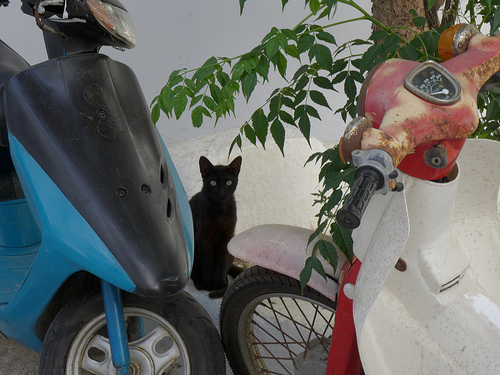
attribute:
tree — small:
[130, 0, 499, 317]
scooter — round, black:
[4, 1, 204, 340]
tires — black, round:
[38, 265, 355, 373]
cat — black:
[177, 157, 261, 271]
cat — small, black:
[186, 153, 249, 286]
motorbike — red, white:
[18, 19, 315, 372]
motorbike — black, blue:
[34, 141, 249, 365]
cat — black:
[181, 155, 265, 289]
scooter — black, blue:
[2, 61, 186, 359]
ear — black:
[195, 150, 212, 172]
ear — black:
[225, 150, 244, 167]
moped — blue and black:
[11, 55, 211, 373]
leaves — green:
[162, 12, 332, 113]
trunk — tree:
[370, 0, 439, 59]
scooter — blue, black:
[0, 1, 226, 373]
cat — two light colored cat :
[166, 80, 254, 305]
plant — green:
[170, 50, 292, 127]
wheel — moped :
[217, 267, 356, 372]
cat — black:
[186, 142, 243, 284]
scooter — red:
[221, 21, 497, 373]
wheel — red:
[201, 262, 361, 373]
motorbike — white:
[203, 15, 492, 359]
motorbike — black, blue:
[184, 136, 284, 309]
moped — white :
[218, 20, 498, 373]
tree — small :
[151, 13, 484, 214]